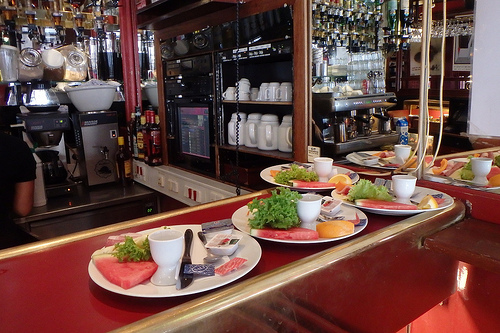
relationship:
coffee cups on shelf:
[222, 74, 292, 101] [219, 96, 295, 115]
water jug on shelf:
[273, 110, 293, 156] [219, 140, 294, 166]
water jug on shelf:
[254, 110, 281, 153] [219, 140, 294, 166]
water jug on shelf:
[243, 112, 258, 147] [219, 140, 294, 166]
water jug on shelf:
[224, 106, 248, 152] [219, 140, 294, 166]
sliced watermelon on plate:
[91, 253, 158, 290] [82, 224, 261, 302]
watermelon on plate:
[250, 226, 320, 240] [226, 194, 368, 245]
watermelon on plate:
[355, 199, 418, 210] [339, 180, 450, 218]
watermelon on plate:
[287, 179, 336, 188] [257, 156, 357, 188]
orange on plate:
[317, 218, 359, 239] [229, 188, 368, 243]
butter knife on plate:
[178, 227, 194, 292] [82, 224, 261, 302]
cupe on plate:
[145, 229, 186, 278] [82, 224, 261, 302]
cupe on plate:
[292, 191, 323, 223] [226, 194, 368, 245]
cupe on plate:
[390, 174, 420, 201] [357, 180, 449, 216]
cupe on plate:
[305, 156, 337, 187] [262, 161, 361, 192]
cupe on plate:
[388, 141, 415, 165] [346, 148, 406, 172]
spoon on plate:
[197, 231, 220, 263] [82, 224, 261, 302]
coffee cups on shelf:
[256, 82, 292, 102] [218, 100, 295, 114]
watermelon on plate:
[251, 226, 320, 240] [232, 199, 358, 245]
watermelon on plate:
[355, 194, 422, 212] [354, 182, 453, 214]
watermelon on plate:
[292, 178, 338, 190] [262, 159, 354, 191]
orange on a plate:
[316, 220, 355, 239] [226, 194, 368, 245]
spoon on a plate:
[196, 228, 221, 266] [82, 224, 261, 302]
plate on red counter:
[86, 224, 262, 298] [11, 260, 97, 330]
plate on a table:
[88, 228, 261, 298] [1, 251, 92, 331]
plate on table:
[227, 186, 378, 261] [0, 142, 500, 331]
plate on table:
[328, 169, 458, 228] [0, 142, 500, 331]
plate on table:
[247, 155, 372, 194] [0, 142, 500, 331]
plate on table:
[341, 140, 431, 179] [0, 142, 500, 331]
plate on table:
[86, 224, 262, 298] [0, 142, 500, 331]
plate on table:
[231, 194, 370, 244] [0, 142, 500, 331]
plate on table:
[331, 175, 455, 217] [0, 142, 500, 331]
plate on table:
[251, 154, 361, 193] [0, 142, 500, 331]